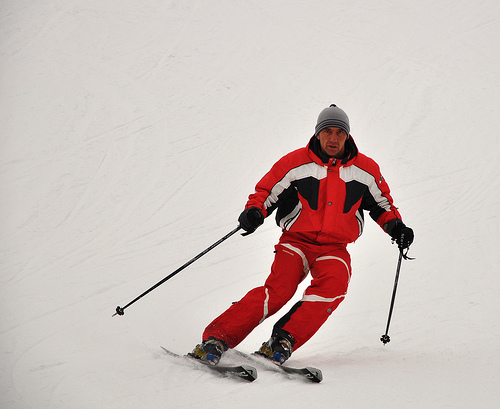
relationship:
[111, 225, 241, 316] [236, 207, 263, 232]
pole in hand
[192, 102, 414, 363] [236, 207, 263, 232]
man has hand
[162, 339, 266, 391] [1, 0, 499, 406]
ski on snow